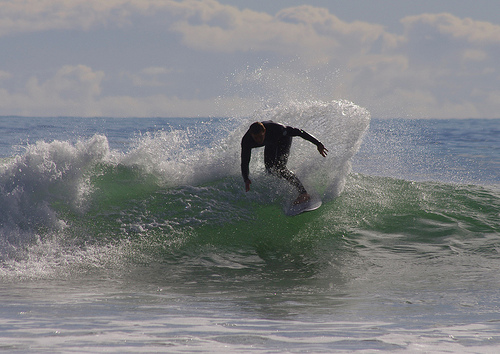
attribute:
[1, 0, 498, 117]
clouds — puffy, white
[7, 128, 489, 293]
waves — large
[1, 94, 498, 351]
water — green, wavy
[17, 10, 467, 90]
clouds — white, fluffy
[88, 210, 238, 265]
water — splashing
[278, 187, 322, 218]
surfboard — white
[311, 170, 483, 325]
water — blue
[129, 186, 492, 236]
wave — green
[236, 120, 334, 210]
surfer — leaning forward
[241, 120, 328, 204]
man — bent forward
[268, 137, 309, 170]
wetsuit — black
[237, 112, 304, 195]
wetsuit — black